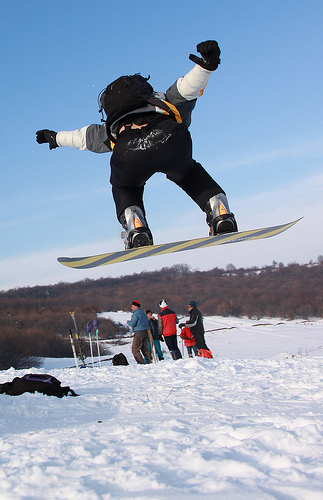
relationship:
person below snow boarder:
[157, 300, 182, 362] [37, 41, 238, 251]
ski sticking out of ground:
[147, 328, 157, 362] [1, 311, 322, 499]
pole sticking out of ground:
[93, 321, 103, 370] [1, 311, 322, 499]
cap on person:
[133, 300, 141, 308] [127, 300, 153, 363]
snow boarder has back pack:
[37, 41, 238, 251] [99, 74, 178, 144]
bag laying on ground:
[1, 373, 78, 397] [1, 311, 322, 499]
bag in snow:
[1, 373, 78, 397] [1, 312, 322, 499]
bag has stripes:
[1, 373, 78, 397] [27, 373, 54, 383]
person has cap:
[179, 301, 213, 359] [189, 300, 197, 308]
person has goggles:
[179, 301, 213, 359] [188, 305, 193, 308]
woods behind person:
[1, 254, 322, 372] [179, 301, 213, 359]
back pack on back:
[99, 74, 178, 144] [116, 92, 171, 136]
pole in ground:
[68, 329, 80, 369] [1, 311, 322, 499]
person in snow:
[179, 301, 213, 359] [1, 312, 322, 499]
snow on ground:
[1, 312, 322, 499] [1, 311, 322, 499]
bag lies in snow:
[1, 373, 78, 397] [1, 312, 322, 499]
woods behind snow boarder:
[1, 254, 322, 372] [37, 41, 238, 251]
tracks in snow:
[100, 317, 319, 421] [1, 312, 322, 499]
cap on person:
[158, 299, 168, 308] [157, 300, 182, 362]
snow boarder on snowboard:
[37, 41, 238, 251] [57, 217, 304, 269]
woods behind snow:
[1, 254, 322, 372] [1, 312, 322, 499]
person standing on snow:
[179, 301, 213, 359] [1, 312, 322, 499]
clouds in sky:
[2, 132, 322, 290] [1, 0, 322, 293]